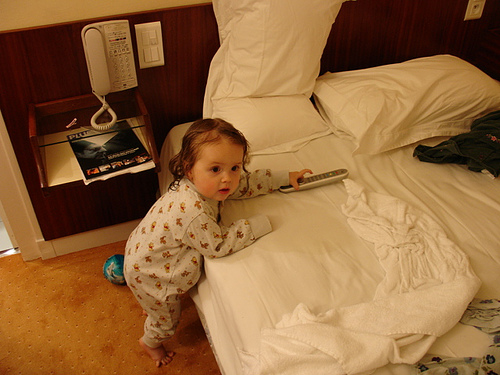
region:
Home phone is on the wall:
[47, 11, 169, 143]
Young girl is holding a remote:
[170, 126, 390, 219]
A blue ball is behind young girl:
[88, 244, 179, 309]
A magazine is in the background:
[63, 113, 163, 195]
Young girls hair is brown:
[163, 113, 272, 205]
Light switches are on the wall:
[132, 16, 182, 79]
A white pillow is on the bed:
[329, 58, 499, 143]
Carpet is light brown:
[8, 284, 150, 374]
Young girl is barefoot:
[119, 327, 193, 370]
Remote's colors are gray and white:
[266, 156, 381, 203]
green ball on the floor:
[94, 250, 141, 285]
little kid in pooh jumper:
[120, 113, 295, 365]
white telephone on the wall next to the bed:
[77, 2, 144, 105]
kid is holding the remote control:
[146, 117, 354, 191]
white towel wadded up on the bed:
[240, 174, 496, 373]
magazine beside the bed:
[58, 107, 159, 179]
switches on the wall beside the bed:
[130, 14, 170, 75]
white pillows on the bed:
[204, 3, 495, 155]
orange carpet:
[2, 237, 227, 373]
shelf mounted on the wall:
[18, 90, 163, 190]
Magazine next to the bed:
[62, 121, 158, 188]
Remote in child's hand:
[281, 164, 351, 197]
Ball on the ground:
[101, 249, 133, 294]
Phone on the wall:
[84, 17, 145, 134]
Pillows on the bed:
[209, 0, 495, 158]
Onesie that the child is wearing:
[121, 169, 291, 341]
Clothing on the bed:
[414, 101, 498, 193]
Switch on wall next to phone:
[135, 19, 170, 76]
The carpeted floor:
[0, 232, 221, 372]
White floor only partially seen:
[0, 217, 15, 257]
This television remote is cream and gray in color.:
[278, 156, 355, 207]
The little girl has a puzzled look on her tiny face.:
[174, 133, 256, 208]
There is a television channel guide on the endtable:
[60, 107, 152, 192]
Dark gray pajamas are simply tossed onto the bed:
[409, 84, 496, 199]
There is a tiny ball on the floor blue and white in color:
[100, 252, 137, 284]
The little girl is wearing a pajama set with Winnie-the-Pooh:
[124, 110, 259, 364]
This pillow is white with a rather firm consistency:
[219, 0, 324, 101]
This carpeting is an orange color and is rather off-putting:
[18, 295, 87, 372]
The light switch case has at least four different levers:
[134, 30, 169, 72]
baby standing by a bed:
[120, 117, 312, 361]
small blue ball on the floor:
[103, 252, 133, 283]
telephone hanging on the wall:
[81, 19, 141, 115]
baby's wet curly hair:
[168, 112, 254, 201]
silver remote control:
[279, 169, 352, 194]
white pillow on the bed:
[316, 45, 498, 169]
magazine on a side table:
[63, 122, 153, 192]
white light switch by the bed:
[133, 18, 167, 81]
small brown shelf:
[23, 94, 162, 189]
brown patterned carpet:
[1, 245, 223, 373]